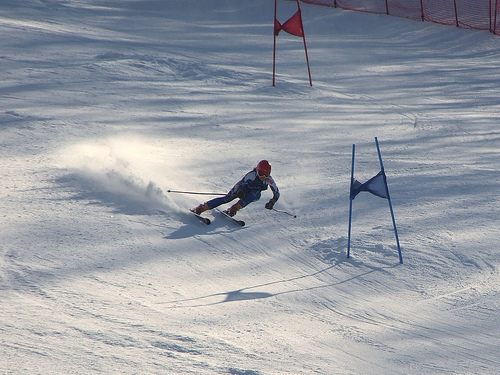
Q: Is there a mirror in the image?
A: No, there are no mirrors.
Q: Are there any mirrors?
A: No, there are no mirrors.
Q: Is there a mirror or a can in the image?
A: No, there are no mirrors or cans.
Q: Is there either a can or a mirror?
A: No, there are no mirrors or cans.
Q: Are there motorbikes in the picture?
A: No, there are no motorbikes.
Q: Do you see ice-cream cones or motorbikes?
A: No, there are no motorbikes or ice-cream cones.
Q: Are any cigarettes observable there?
A: No, there are no cigarettes.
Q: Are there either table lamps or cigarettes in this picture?
A: No, there are no cigarettes or table lamps.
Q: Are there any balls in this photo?
A: No, there are no balls.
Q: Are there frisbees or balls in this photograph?
A: No, there are no balls or frisbees.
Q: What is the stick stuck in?
A: The stick is stuck in the snow.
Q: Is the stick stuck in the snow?
A: Yes, the stick is stuck in the snow.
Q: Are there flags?
A: Yes, there is a flag.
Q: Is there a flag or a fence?
A: Yes, there is a flag.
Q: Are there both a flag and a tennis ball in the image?
A: No, there is a flag but no tennis balls.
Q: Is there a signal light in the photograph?
A: No, there are no traffic lights.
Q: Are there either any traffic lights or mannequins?
A: No, there are no traffic lights or mannequins.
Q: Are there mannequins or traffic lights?
A: No, there are no traffic lights or mannequins.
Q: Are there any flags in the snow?
A: Yes, there is a flag in the snow.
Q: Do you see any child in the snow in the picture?
A: No, there is a flag in the snow.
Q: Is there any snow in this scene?
A: Yes, there is snow.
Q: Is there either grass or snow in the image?
A: Yes, there is snow.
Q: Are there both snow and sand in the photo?
A: No, there is snow but no sand.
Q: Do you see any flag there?
A: Yes, there is a flag.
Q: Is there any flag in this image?
A: Yes, there is a flag.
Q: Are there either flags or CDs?
A: Yes, there is a flag.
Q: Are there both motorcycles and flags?
A: No, there is a flag but no motorcycles.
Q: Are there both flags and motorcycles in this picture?
A: No, there is a flag but no motorcycles.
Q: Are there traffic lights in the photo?
A: No, there are no traffic lights.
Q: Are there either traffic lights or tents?
A: No, there are no traffic lights or tents.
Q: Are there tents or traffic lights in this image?
A: No, there are no traffic lights or tents.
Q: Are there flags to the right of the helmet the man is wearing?
A: Yes, there is a flag to the right of the helmet.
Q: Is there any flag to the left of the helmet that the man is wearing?
A: No, the flag is to the right of the helmet.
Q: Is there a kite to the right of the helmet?
A: No, there is a flag to the right of the helmet.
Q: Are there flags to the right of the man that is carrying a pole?
A: Yes, there is a flag to the right of the man.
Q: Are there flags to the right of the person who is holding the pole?
A: Yes, there is a flag to the right of the man.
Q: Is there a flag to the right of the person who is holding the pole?
A: Yes, there is a flag to the right of the man.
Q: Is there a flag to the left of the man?
A: No, the flag is to the right of the man.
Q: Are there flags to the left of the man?
A: No, the flag is to the right of the man.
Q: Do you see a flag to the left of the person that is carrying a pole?
A: No, the flag is to the right of the man.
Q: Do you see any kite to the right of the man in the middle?
A: No, there is a flag to the right of the man.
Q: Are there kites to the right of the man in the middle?
A: No, there is a flag to the right of the man.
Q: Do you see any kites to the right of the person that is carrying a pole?
A: No, there is a flag to the right of the man.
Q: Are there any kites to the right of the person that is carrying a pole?
A: No, there is a flag to the right of the man.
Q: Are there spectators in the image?
A: No, there are no spectators.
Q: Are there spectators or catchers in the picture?
A: No, there are no spectators or catchers.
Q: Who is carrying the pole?
A: The man is carrying the pole.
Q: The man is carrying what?
A: The man is carrying a pole.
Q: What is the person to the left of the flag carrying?
A: The man is carrying a pole.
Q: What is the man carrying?
A: The man is carrying a pole.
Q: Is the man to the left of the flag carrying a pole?
A: Yes, the man is carrying a pole.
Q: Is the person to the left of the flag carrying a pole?
A: Yes, the man is carrying a pole.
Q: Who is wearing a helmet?
A: The man is wearing a helmet.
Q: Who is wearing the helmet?
A: The man is wearing a helmet.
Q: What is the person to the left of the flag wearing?
A: The man is wearing a helmet.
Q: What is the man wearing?
A: The man is wearing a helmet.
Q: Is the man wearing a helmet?
A: Yes, the man is wearing a helmet.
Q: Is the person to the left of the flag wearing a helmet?
A: Yes, the man is wearing a helmet.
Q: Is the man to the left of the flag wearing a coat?
A: No, the man is wearing a helmet.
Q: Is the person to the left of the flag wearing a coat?
A: No, the man is wearing a helmet.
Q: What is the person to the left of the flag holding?
A: The man is holding the pole.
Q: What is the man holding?
A: The man is holding the pole.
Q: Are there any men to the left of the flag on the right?
A: Yes, there is a man to the left of the flag.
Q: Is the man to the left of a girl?
A: No, the man is to the left of the flag.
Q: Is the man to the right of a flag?
A: No, the man is to the left of a flag.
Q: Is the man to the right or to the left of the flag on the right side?
A: The man is to the left of the flag.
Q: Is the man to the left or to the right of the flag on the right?
A: The man is to the left of the flag.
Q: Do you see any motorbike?
A: No, there are no motorcycles.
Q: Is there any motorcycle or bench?
A: No, there are no motorcycles or benches.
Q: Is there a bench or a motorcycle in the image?
A: No, there are no motorcycles or benches.